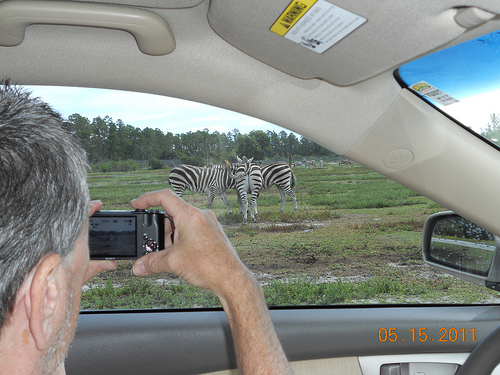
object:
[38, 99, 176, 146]
man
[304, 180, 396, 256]
grass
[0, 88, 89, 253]
hair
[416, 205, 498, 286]
mirror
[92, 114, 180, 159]
tree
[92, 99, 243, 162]
distance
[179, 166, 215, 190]
stripe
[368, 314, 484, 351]
date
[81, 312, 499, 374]
interior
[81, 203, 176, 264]
camera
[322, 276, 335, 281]
water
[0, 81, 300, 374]
man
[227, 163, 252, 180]
tail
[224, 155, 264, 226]
animal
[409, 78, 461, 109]
sticker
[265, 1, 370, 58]
label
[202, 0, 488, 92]
visor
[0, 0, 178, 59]
handle